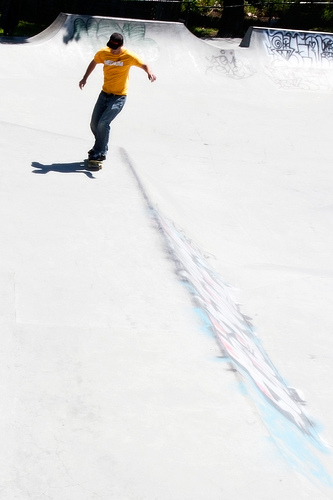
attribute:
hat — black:
[106, 33, 124, 52]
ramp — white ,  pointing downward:
[0, 39, 329, 498]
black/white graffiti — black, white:
[261, 28, 332, 67]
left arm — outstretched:
[125, 50, 155, 82]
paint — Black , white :
[264, 31, 320, 55]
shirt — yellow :
[92, 46, 141, 92]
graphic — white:
[103, 58, 123, 67]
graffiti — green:
[61, 15, 165, 49]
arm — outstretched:
[77, 48, 102, 87]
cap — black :
[105, 32, 123, 49]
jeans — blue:
[84, 87, 127, 163]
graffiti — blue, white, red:
[150, 206, 328, 454]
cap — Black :
[106, 31, 124, 48]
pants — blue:
[81, 90, 140, 168]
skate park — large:
[171, 58, 255, 130]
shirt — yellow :
[90, 45, 147, 100]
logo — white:
[101, 57, 126, 68]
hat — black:
[102, 30, 126, 48]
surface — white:
[0, 12, 332, 498]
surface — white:
[25, 177, 307, 485]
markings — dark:
[119, 141, 324, 449]